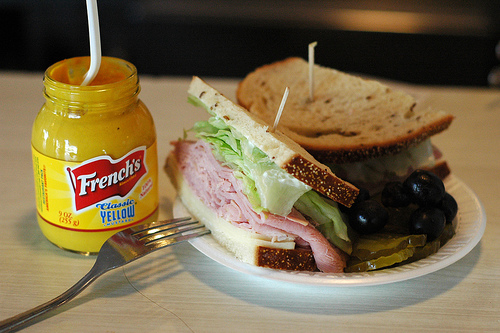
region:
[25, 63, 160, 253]
a jar of mustard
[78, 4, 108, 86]
a plastic utensil in the mustard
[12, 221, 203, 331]
a silver fork on the plate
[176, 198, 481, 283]
a white paper plate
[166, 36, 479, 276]
a sandwich on a paper plate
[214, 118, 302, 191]
lettuce on the sandwich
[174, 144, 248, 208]
the meat on the sandwich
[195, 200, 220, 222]
the cheese on the sandwich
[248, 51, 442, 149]
the bread on the sandwich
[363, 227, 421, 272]
pickles next to the sandwich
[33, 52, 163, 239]
Jar of mustard with a red logo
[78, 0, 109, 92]
White plastic fork sticking out of a jar of mustard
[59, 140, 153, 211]
Drawing of a red flag with the word French's written in white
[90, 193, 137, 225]
The words Clearly Yellow written in blue on a yellow background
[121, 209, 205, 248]
Four tines of a metal fork shining and reflecting light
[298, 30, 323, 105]
Wooden toothpick stuck through the top of a sandwhich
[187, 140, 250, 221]
Layer of pink colored meat on a sandwhich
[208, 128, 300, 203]
Thick amount of lettuce touching the top bun of a sandwhich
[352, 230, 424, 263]
Thinly slice green pickles with darker edges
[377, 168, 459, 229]
Round black olives in a small pile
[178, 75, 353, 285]
a sandwich half with lettuce and ham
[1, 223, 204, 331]
a shiny metal fork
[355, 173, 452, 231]
a small mound of black olives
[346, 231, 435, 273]
a few slices of green pickles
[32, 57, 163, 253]
a glass jar of yellow custard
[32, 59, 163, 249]
a jar of "French's" brand of mustard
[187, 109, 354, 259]
green crispy lettuce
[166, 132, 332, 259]
rows of sliced ham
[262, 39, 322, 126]
wooden toothpicks sticking into sandwich halves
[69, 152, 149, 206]
a red flag with white writing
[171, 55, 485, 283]
sandwich on paper plate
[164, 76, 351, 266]
half slice of sandwich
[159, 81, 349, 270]
lettuce and ham in bread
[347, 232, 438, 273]
pickle slices on plate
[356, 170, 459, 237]
pile of black olives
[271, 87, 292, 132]
toothpick in top of bread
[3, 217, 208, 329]
back of fork on plate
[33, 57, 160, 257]
uncovered jar of mustard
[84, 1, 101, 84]
plastic utensil in mustard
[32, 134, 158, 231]
label on mustard jar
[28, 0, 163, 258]
Plastic utensil in jar of mustard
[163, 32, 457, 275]
Sandwich on a Styrofoam plate.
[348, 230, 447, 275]
Pickles on a styrofoam plate.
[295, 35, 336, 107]
Toothpick stuck in bread.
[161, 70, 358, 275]
Lettuce and ham in between two pieces of bread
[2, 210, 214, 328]
metal fork on a counter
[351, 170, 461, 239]
olives on a styrofoam plate.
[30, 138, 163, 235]
yellow label on jar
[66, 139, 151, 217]
Red flag with white lettering on label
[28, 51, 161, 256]
open jar of yellow mustard